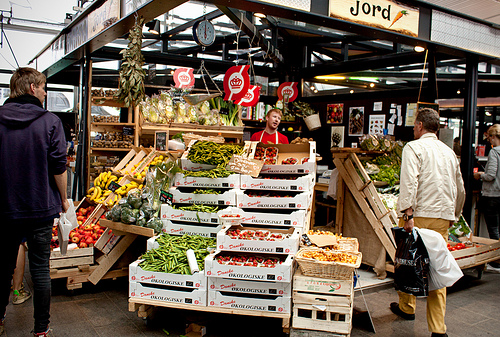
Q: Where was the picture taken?
A: At a outside market.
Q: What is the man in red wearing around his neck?
A: An apron.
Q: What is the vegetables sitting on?
A: Pallets.